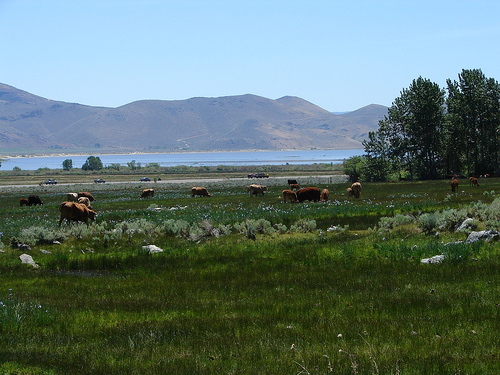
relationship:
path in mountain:
[175, 128, 210, 148] [201, 119, 361, 151]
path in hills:
[175, 128, 210, 148] [2, 82, 365, 157]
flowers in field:
[208, 202, 398, 213] [12, 197, 494, 370]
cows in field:
[51, 179, 373, 226] [12, 197, 494, 370]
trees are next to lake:
[366, 71, 499, 188] [5, 154, 370, 165]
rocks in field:
[12, 240, 448, 271] [12, 197, 494, 370]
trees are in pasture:
[366, 71, 499, 188] [19, 157, 489, 206]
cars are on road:
[38, 174, 165, 186] [3, 174, 351, 183]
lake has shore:
[5, 154, 370, 165] [5, 145, 361, 156]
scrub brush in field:
[17, 215, 327, 238] [12, 197, 494, 370]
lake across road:
[5, 154, 370, 165] [3, 174, 351, 183]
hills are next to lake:
[2, 82, 365, 157] [5, 154, 370, 165]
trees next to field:
[366, 71, 499, 188] [12, 197, 494, 370]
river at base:
[5, 154, 370, 165] [7, 147, 378, 150]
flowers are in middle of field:
[208, 202, 398, 213] [12, 197, 494, 370]